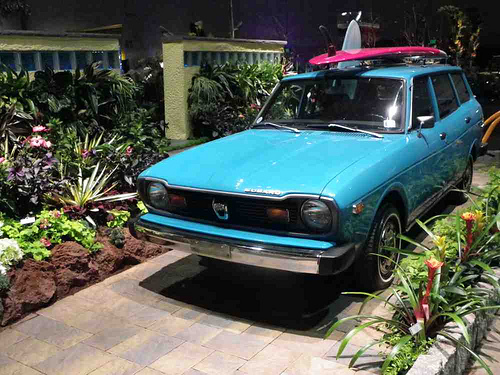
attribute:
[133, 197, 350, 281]
bumper — SILVER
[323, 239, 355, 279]
black cap — plastic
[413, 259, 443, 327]
redplant — red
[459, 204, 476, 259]
redplant — red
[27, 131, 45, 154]
redplant — red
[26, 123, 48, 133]
redplant — red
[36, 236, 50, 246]
redplant — red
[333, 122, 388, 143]
wiper — chrome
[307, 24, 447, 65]
surfboard — pink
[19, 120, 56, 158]
flowers — pink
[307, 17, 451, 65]
surfboard — white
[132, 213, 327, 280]
bumper — chrome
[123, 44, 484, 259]
car — blue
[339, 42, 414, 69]
surfboard — pink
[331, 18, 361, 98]
surfboard — white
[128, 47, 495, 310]
car — vintage, BLUE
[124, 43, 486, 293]
car — old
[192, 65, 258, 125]
plants — green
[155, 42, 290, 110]
wall — yellow